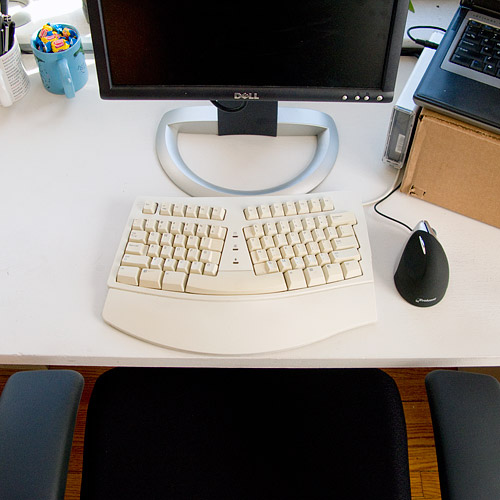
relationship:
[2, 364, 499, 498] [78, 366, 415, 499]
chair has seat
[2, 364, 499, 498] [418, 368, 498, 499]
chair has arm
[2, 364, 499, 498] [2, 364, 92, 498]
chair has arm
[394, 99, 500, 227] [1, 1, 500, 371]
box on table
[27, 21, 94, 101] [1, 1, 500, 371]
cup on table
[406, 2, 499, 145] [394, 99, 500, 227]
laptop on box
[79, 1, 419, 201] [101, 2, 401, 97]
computer has screen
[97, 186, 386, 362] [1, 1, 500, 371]
keyboard on table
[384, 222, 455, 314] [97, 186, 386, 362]
mouse beside keyboard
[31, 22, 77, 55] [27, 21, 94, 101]
gum inside of cup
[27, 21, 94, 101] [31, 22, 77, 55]
cup has gum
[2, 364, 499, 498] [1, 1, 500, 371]
chair in front of table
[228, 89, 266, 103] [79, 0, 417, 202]
dell on monitor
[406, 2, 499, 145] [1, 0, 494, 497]
laptop in picture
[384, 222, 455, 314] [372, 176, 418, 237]
mouse has cord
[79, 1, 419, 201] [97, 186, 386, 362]
computer has keyboard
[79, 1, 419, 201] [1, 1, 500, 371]
computer on table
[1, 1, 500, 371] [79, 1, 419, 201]
table has computer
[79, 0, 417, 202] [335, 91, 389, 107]
monitor has control buttons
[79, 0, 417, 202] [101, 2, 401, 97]
monitor has screen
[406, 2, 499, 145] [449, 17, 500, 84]
laptop has keyboard